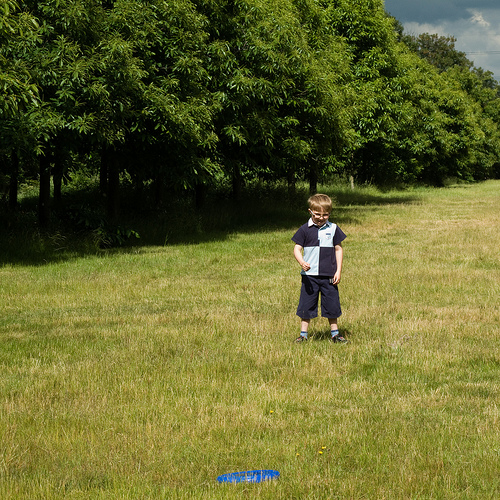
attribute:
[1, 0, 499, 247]
trees — green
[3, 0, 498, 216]
trees — green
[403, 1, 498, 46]
sky — Dark blue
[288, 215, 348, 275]
checkered shirt — blue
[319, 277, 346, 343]
leg — boy's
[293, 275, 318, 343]
leg — boy's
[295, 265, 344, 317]
shorts — blue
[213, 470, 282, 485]
frisbee — blue, circular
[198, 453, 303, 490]
frisbee — blue, plastic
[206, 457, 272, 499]
frisbee — Blue 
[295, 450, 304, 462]
flower — Yellow 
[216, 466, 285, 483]
frisbee — blue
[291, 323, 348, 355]
shoes — blue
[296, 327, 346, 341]
socks — blue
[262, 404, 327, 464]
dandelions — yellow 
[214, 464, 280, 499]
frisbee — blue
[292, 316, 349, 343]
socks — Blue 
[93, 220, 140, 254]
plant — green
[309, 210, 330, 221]
glasses — brown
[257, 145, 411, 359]
boy — little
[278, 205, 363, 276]
shirt — white tee, blue 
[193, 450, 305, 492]
frisbee — blue 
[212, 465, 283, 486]
frisbee — Blue 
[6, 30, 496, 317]
field — bordered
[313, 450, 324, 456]
flower — Yellow 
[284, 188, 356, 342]
boy — young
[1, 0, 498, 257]
tree row — green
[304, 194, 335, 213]
boy's head — brown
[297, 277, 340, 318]
shorts — Black 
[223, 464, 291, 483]
frisbee — blue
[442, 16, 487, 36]
sky — blue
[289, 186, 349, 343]
boy — black, little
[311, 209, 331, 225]
face — boy's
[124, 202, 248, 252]
shadows — Dark 